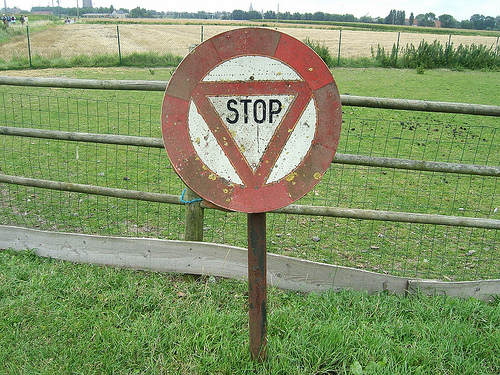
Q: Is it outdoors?
A: Yes, it is outdoors.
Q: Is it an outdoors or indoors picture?
A: It is outdoors.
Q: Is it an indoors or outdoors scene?
A: It is outdoors.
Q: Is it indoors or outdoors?
A: It is outdoors.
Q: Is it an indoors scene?
A: No, it is outdoors.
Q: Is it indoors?
A: No, it is outdoors.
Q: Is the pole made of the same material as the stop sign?
A: No, the pole is made of wood and the stop sign is made of metal.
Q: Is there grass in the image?
A: Yes, there is grass.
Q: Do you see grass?
A: Yes, there is grass.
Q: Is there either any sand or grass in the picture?
A: Yes, there is grass.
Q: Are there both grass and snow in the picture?
A: No, there is grass but no snow.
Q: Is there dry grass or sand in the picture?
A: Yes, there is dry grass.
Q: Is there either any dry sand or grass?
A: Yes, there is dry grass.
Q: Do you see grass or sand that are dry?
A: Yes, the grass is dry.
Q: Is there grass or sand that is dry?
A: Yes, the grass is dry.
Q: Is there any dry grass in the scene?
A: Yes, there is dry grass.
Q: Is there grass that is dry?
A: Yes, there is grass that is dry.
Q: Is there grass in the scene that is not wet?
A: Yes, there is dry grass.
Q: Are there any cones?
A: No, there are no cones.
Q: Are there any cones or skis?
A: No, there are no cones or skis.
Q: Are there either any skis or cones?
A: No, there are no cones or skis.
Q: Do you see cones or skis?
A: No, there are no cones or skis.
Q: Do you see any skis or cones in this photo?
A: No, there are no cones or skis.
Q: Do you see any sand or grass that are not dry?
A: No, there is grass but it is dry.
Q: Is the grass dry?
A: Yes, the grass is dry.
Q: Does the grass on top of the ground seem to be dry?
A: Yes, the grass is dry.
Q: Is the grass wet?
A: No, the grass is dry.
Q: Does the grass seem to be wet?
A: No, the grass is dry.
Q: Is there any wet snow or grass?
A: No, there is grass but it is dry.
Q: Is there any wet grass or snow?
A: No, there is grass but it is dry.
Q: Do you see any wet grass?
A: No, there is grass but it is dry.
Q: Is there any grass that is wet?
A: No, there is grass but it is dry.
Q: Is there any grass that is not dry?
A: No, there is grass but it is dry.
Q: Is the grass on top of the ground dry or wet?
A: The grass is dry.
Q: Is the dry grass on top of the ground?
A: Yes, the grass is on top of the ground.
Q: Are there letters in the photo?
A: Yes, there are letters.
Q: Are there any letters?
A: Yes, there are letters.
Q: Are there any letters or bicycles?
A: Yes, there are letters.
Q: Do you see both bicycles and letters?
A: No, there are letters but no bicycles.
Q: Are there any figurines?
A: No, there are no figurines.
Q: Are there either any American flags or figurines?
A: No, there are no figurines or American flags.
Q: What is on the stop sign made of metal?
A: The letters are on the stop sign.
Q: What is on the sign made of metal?
A: The letters are on the stop sign.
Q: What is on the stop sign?
A: The letters are on the stop sign.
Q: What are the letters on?
A: The letters are on the stop sign.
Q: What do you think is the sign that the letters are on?
A: The sign is a stop sign.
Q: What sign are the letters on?
A: The letters are on the stop sign.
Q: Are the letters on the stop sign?
A: Yes, the letters are on the stop sign.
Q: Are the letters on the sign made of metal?
A: Yes, the letters are on the stop sign.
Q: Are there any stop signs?
A: Yes, there is a stop sign.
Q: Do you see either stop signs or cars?
A: Yes, there is a stop sign.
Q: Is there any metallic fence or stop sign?
A: Yes, there is a metal stop sign.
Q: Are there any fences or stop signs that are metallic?
A: Yes, the stop sign is metallic.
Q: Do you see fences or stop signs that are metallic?
A: Yes, the stop sign is metallic.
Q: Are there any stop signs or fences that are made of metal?
A: Yes, the stop sign is made of metal.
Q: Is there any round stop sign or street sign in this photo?
A: Yes, there is a round stop sign.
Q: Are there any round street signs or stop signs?
A: Yes, there is a round stop sign.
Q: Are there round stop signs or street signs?
A: Yes, there is a round stop sign.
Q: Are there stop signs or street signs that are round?
A: Yes, the stop sign is round.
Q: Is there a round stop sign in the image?
A: Yes, there is a round stop sign.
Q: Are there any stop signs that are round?
A: Yes, there is a stop sign that is round.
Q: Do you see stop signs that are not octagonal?
A: Yes, there is an round stop sign.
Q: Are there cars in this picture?
A: No, there are no cars.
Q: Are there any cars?
A: No, there are no cars.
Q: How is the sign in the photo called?
A: The sign is a stop sign.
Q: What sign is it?
A: The sign is a stop sign.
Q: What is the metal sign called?
A: The sign is a stop sign.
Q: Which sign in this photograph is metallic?
A: The sign is a stop sign.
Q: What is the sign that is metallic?
A: The sign is a stop sign.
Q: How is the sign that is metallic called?
A: The sign is a stop sign.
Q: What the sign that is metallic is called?
A: The sign is a stop sign.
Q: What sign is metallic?
A: The sign is a stop sign.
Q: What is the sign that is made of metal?
A: The sign is a stop sign.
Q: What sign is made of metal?
A: The sign is a stop sign.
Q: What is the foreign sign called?
A: The sign is a stop sign.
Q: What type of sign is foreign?
A: The sign is a stop sign.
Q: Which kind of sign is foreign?
A: The sign is a stop sign.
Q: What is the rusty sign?
A: The sign is a stop sign.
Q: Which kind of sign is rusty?
A: The sign is a stop sign.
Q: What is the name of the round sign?
A: The sign is a stop sign.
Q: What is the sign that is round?
A: The sign is a stop sign.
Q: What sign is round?
A: The sign is a stop sign.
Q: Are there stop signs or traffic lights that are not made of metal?
A: No, there is a stop sign but it is made of metal.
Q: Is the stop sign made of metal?
A: Yes, the stop sign is made of metal.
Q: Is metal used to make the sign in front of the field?
A: Yes, the stop sign is made of metal.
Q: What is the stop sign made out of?
A: The stop sign is made of metal.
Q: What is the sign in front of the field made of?
A: The stop sign is made of metal.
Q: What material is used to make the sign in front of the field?
A: The stop sign is made of metal.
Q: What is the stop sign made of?
A: The stop sign is made of metal.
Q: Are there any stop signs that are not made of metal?
A: No, there is a stop sign but it is made of metal.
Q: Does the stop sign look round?
A: Yes, the stop sign is round.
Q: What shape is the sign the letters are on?
A: The stop sign is round.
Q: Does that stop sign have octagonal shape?
A: No, the stop sign is round.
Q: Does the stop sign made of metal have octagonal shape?
A: No, the stop sign is round.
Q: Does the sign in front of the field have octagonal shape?
A: No, the stop sign is round.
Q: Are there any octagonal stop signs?
A: No, there is a stop sign but it is round.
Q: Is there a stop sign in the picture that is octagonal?
A: No, there is a stop sign but it is round.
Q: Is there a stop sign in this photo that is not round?
A: No, there is a stop sign but it is round.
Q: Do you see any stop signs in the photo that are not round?
A: No, there is a stop sign but it is round.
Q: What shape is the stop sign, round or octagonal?
A: The stop sign is round.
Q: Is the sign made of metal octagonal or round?
A: The stop sign is round.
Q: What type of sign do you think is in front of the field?
A: The sign is a stop sign.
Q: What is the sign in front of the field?
A: The sign is a stop sign.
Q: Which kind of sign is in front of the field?
A: The sign is a stop sign.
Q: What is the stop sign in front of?
A: The stop sign is in front of the field.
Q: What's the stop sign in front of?
A: The stop sign is in front of the field.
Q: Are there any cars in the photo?
A: No, there are no cars.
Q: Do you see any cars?
A: No, there are no cars.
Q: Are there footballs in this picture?
A: No, there are no footballs.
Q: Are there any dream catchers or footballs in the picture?
A: No, there are no footballs or dream catchers.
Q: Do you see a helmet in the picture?
A: No, there are no helmets.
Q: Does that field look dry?
A: Yes, the field is dry.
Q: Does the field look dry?
A: Yes, the field is dry.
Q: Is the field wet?
A: No, the field is dry.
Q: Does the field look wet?
A: No, the field is dry.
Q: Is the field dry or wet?
A: The field is dry.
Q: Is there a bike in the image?
A: No, there are no bikes.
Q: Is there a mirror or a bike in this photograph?
A: No, there are no bikes or mirrors.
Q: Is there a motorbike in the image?
A: No, there are no motorcycles.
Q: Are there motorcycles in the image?
A: No, there are no motorcycles.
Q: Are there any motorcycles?
A: No, there are no motorcycles.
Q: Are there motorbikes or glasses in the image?
A: No, there are no motorbikes or glasses.